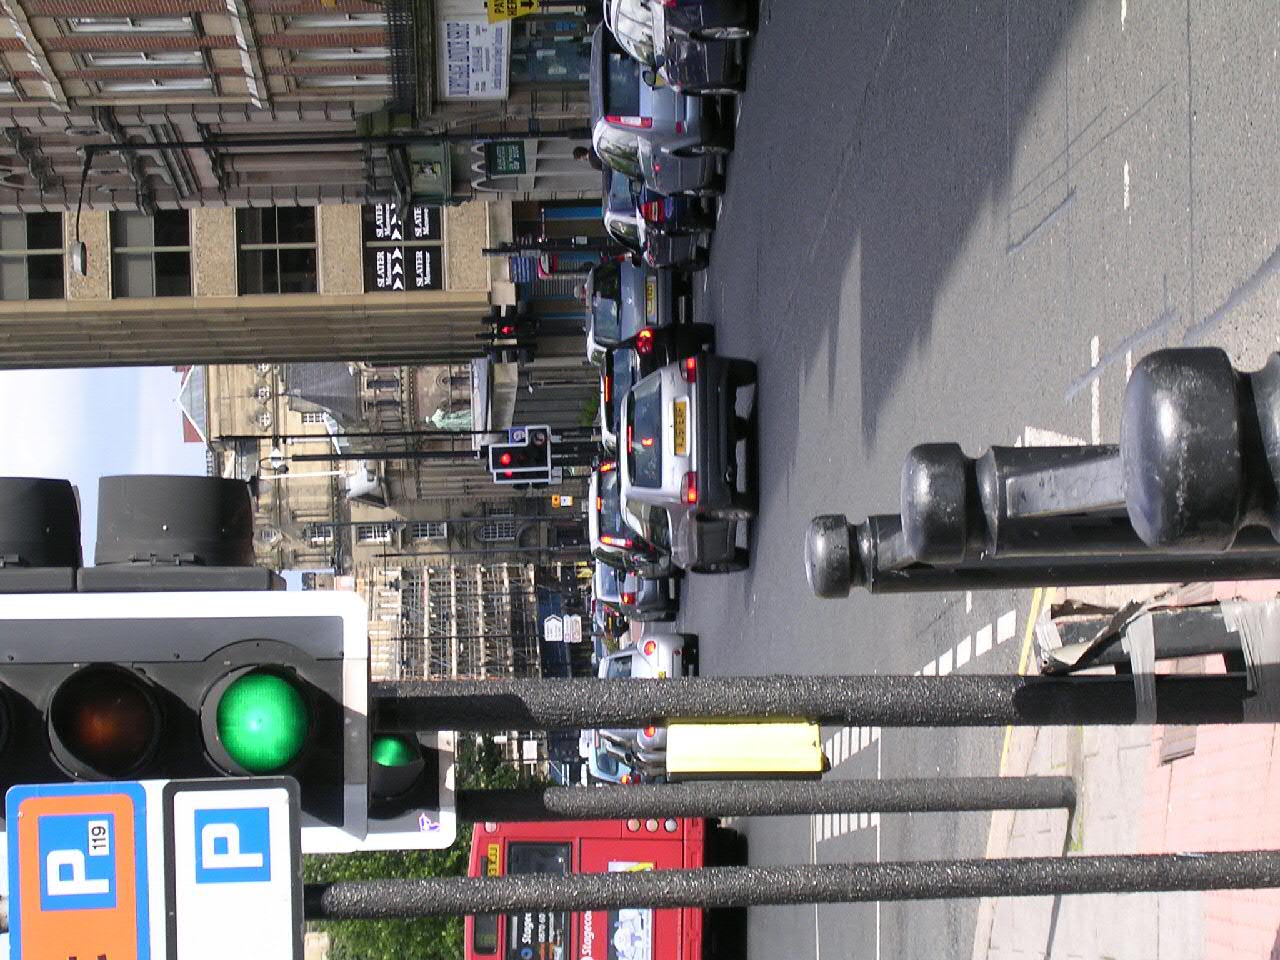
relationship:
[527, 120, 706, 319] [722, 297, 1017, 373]
car on road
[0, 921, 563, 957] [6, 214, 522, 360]
wall on side of building